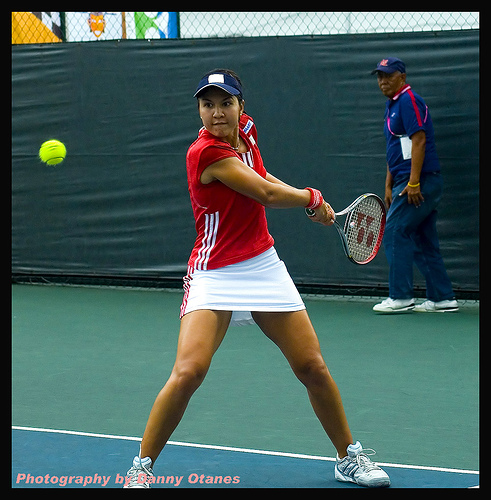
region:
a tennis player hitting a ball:
[37, 30, 386, 312]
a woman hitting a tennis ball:
[36, 65, 387, 274]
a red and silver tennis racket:
[334, 187, 385, 266]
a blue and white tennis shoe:
[333, 438, 391, 487]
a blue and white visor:
[186, 64, 248, 100]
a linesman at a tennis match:
[365, 51, 466, 321]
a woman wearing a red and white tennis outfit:
[169, 64, 338, 325]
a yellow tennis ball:
[33, 134, 71, 167]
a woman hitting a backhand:
[174, 62, 387, 275]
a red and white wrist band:
[301, 181, 324, 214]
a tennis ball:
[38, 137, 64, 162]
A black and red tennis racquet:
[334, 192, 385, 261]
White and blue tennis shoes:
[322, 439, 393, 483]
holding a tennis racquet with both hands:
[291, 183, 385, 262]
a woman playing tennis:
[122, 65, 388, 484]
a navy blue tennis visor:
[188, 71, 244, 102]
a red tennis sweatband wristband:
[295, 180, 321, 212]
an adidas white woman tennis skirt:
[174, 240, 296, 316]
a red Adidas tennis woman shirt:
[184, 109, 268, 264]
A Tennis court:
[10, 282, 479, 486]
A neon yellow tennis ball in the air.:
[35, 137, 72, 169]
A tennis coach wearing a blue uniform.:
[370, 55, 457, 317]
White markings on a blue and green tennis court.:
[39, 344, 125, 461]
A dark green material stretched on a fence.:
[27, 47, 471, 65]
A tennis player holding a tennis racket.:
[125, 68, 387, 492]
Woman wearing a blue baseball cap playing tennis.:
[192, 68, 245, 143]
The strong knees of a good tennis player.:
[153, 359, 391, 398]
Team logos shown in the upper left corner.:
[17, 12, 172, 38]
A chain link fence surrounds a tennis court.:
[185, 15, 485, 29]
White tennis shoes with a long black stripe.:
[373, 296, 462, 314]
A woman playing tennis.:
[38, 87, 388, 292]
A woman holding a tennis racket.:
[255, 130, 405, 293]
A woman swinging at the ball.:
[34, 118, 408, 273]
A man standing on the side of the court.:
[355, 68, 432, 259]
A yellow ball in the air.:
[27, 132, 86, 195]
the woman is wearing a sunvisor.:
[163, 49, 255, 104]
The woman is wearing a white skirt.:
[156, 251, 363, 314]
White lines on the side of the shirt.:
[172, 207, 226, 277]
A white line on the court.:
[41, 412, 416, 482]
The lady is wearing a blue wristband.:
[297, 181, 325, 219]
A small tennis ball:
[27, 127, 73, 176]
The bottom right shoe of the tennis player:
[325, 443, 395, 481]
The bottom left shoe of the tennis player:
[119, 449, 150, 494]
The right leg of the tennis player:
[269, 317, 356, 453]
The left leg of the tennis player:
[127, 312, 243, 453]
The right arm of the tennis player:
[220, 158, 312, 230]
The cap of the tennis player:
[188, 63, 244, 99]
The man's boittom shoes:
[369, 288, 465, 327]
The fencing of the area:
[179, 9, 481, 41]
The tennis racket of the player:
[333, 190, 387, 280]